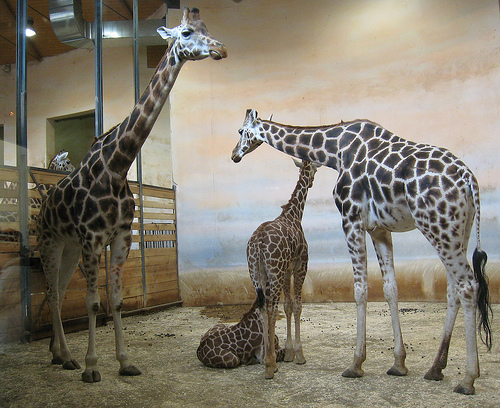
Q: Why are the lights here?
A: This is an artificial environment.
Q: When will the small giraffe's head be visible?
A: When it stands up.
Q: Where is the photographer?
A: Facing the giraffes.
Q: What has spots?
A: The giraffes.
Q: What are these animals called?
A: Giraffes.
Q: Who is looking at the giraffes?
A: The photographer.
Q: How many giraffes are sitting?
A: One.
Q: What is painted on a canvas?
A: A sky and grass.